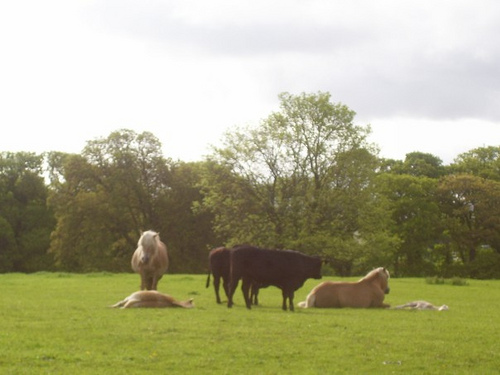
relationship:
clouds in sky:
[0, 1, 498, 201] [0, 0, 499, 203]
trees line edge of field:
[0, 89, 497, 274] [0, 276, 498, 373]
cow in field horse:
[227, 242, 325, 312] [127, 228, 169, 288]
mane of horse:
[337, 260, 394, 282] [302, 267, 407, 312]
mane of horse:
[118, 212, 182, 263] [54, 197, 226, 341]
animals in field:
[211, 235, 346, 306] [1, 265, 452, 360]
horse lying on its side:
[397, 290, 452, 322] [413, 300, 458, 322]